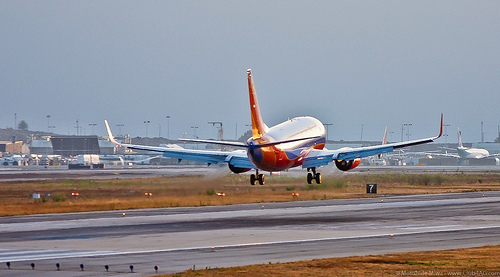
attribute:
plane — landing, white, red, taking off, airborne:
[105, 68, 443, 184]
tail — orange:
[247, 70, 269, 138]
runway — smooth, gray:
[0, 191, 499, 273]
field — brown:
[0, 172, 499, 216]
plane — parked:
[427, 130, 499, 167]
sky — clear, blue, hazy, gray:
[2, 0, 499, 145]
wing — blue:
[304, 115, 445, 169]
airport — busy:
[1, 111, 497, 275]